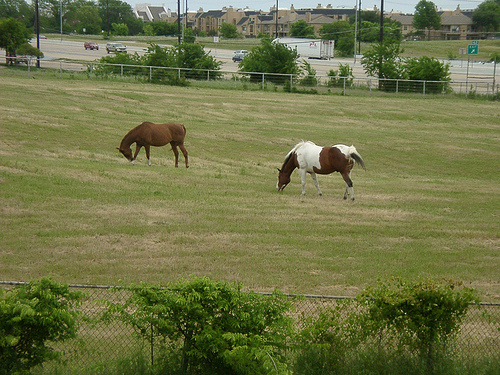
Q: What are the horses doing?
A: Grazing.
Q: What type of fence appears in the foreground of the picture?
A: Chain link.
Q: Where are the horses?
A: Field.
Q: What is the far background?
A: Line of houses.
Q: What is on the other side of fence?
A: Street with traffic.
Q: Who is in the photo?
A: Two horses.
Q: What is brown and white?
A: Closest horse.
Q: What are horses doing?
A: Grazing.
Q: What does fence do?
A: Keeps horses inside.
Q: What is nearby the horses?
A: A highway.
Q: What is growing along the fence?
A: Bushes.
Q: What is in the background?
A: A community.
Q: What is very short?
A: Grass.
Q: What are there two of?
A: Horses.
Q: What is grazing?
A: Horses.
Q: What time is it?
A: Afternoon.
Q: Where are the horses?
A: In the grass.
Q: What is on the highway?
A: Vehicles.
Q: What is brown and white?
A: The horse.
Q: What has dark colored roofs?
A: The buildings.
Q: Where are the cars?
A: Behind the fence.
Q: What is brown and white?
A: Horse.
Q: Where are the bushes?
A: On fence.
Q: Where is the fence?
A: Around horses.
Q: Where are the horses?
A: In fenced area.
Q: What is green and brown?
A: Grass.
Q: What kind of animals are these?
A: Horses.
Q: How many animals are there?
A: Two.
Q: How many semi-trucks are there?
A: One.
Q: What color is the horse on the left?
A: Brown.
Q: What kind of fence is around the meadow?
A: Chainlink.